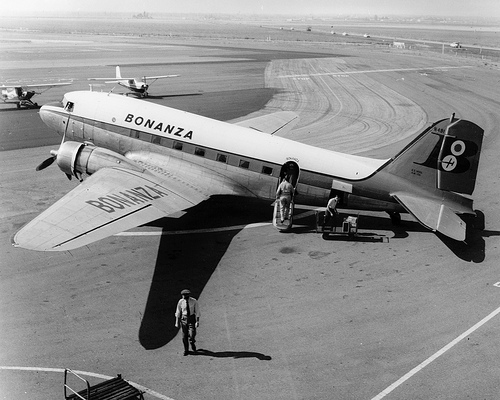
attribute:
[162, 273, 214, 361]
person — walking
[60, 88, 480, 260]
plane — parked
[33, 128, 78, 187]
propeller — metal, small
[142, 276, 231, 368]
man — walking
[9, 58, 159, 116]
planes — smaller, idle